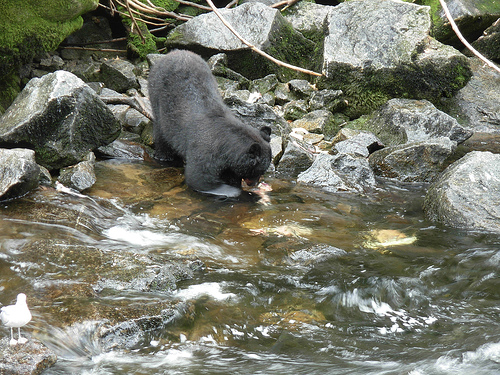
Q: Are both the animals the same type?
A: No, they are birds and bears.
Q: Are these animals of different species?
A: Yes, they are birds and bears.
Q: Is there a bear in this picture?
A: Yes, there is a bear.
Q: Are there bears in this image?
A: Yes, there is a bear.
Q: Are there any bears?
A: Yes, there is a bear.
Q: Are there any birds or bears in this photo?
A: Yes, there is a bear.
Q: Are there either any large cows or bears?
A: Yes, there is a large bear.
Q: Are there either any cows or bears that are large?
A: Yes, the bear is large.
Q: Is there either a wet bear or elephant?
A: Yes, there is a wet bear.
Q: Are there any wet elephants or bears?
A: Yes, there is a wet bear.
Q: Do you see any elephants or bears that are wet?
A: Yes, the bear is wet.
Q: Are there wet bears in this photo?
A: Yes, there is a wet bear.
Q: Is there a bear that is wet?
A: Yes, there is a bear that is wet.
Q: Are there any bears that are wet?
A: Yes, there is a bear that is wet.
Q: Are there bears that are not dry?
A: Yes, there is a wet bear.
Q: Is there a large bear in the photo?
A: Yes, there is a large bear.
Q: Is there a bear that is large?
A: Yes, there is a bear that is large.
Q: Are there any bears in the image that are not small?
A: Yes, there is a large bear.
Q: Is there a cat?
A: No, there are no cats.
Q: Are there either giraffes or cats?
A: No, there are no cats or giraffes.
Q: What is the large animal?
A: The animal is a bear.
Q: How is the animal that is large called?
A: The animal is a bear.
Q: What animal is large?
A: The animal is a bear.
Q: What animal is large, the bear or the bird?
A: The bear is large.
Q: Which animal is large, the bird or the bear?
A: The bear is large.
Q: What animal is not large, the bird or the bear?
A: The bird is not large.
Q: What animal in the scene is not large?
A: The animal is a bird.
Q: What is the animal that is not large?
A: The animal is a bird.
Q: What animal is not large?
A: The animal is a bird.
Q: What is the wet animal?
A: The animal is a bear.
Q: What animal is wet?
A: The animal is a bear.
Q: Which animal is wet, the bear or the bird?
A: The bear is wet.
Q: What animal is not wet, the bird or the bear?
A: The bird is not wet.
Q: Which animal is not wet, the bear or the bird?
A: The bird is not wet.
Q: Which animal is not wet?
A: The animal is a bird.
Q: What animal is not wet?
A: The animal is a bird.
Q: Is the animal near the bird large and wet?
A: Yes, the bear is large and wet.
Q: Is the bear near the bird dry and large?
A: No, the bear is large but wet.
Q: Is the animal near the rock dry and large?
A: No, the bear is large but wet.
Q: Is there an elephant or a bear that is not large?
A: No, there is a bear but it is large.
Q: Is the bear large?
A: Yes, the bear is large.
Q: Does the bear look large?
A: Yes, the bear is large.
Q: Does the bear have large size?
A: Yes, the bear is large.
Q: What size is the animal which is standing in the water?
A: The bear is large.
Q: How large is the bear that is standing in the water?
A: The bear is large.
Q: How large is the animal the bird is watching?
A: The bear is large.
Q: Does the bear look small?
A: No, the bear is large.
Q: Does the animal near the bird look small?
A: No, the bear is large.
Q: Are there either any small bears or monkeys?
A: No, there is a bear but it is large.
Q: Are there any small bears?
A: No, there is a bear but it is large.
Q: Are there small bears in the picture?
A: No, there is a bear but it is large.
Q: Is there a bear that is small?
A: No, there is a bear but it is large.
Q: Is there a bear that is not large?
A: No, there is a bear but it is large.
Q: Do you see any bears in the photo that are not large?
A: No, there is a bear but it is large.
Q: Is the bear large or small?
A: The bear is large.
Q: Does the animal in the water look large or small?
A: The bear is large.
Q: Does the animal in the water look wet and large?
A: Yes, the bear is wet and large.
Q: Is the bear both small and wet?
A: No, the bear is wet but large.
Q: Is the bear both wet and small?
A: No, the bear is wet but large.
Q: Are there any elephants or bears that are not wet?
A: No, there is a bear but it is wet.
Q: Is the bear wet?
A: Yes, the bear is wet.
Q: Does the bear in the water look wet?
A: Yes, the bear is wet.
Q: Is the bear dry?
A: No, the bear is wet.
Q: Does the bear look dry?
A: No, the bear is wet.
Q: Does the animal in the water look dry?
A: No, the bear is wet.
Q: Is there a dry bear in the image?
A: No, there is a bear but it is wet.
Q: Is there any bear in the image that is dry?
A: No, there is a bear but it is wet.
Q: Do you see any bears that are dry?
A: No, there is a bear but it is wet.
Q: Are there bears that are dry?
A: No, there is a bear but it is wet.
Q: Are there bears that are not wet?
A: No, there is a bear but it is wet.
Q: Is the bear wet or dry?
A: The bear is wet.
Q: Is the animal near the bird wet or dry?
A: The bear is wet.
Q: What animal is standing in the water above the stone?
A: The bear is standing in the water.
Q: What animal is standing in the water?
A: The bear is standing in the water.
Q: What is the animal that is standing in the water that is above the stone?
A: The animal is a bear.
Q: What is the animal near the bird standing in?
A: The bear is standing in the water.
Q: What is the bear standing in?
A: The bear is standing in the water.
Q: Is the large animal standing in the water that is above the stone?
A: Yes, the bear is standing in the water.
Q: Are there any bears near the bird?
A: Yes, there is a bear near the bird.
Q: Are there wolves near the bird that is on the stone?
A: No, there is a bear near the bird.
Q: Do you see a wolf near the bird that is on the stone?
A: No, there is a bear near the bird.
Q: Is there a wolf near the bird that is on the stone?
A: No, there is a bear near the bird.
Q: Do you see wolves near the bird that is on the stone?
A: No, there is a bear near the bird.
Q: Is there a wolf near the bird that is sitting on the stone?
A: No, there is a bear near the bird.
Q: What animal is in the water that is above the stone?
A: The bear is in the water.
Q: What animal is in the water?
A: The bear is in the water.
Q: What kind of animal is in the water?
A: The animal is a bear.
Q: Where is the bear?
A: The bear is in the water.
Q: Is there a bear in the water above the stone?
A: Yes, there is a bear in the water.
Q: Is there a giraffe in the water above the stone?
A: No, there is a bear in the water.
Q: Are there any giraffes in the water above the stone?
A: No, there is a bear in the water.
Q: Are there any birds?
A: Yes, there is a bird.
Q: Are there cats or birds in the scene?
A: Yes, there is a bird.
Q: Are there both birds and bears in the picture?
A: Yes, there are both a bird and a bear.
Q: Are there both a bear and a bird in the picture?
A: Yes, there are both a bird and a bear.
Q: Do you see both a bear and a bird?
A: Yes, there are both a bird and a bear.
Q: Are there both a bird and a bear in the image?
A: Yes, there are both a bird and a bear.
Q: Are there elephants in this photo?
A: No, there are no elephants.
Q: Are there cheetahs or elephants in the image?
A: No, there are no elephants or cheetahs.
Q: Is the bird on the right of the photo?
A: No, the bird is on the left of the image.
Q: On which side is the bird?
A: The bird is on the left of the image.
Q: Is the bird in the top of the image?
A: No, the bird is in the bottom of the image.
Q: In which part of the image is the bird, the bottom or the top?
A: The bird is in the bottom of the image.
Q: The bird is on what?
A: The bird is on the stone.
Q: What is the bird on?
A: The bird is on the stone.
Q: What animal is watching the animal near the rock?
A: The bird is watching the bear.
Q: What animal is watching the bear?
A: The bird is watching the bear.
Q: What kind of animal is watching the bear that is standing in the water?
A: The animal is a bird.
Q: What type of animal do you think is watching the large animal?
A: The animal is a bird.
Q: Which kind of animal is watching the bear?
A: The animal is a bird.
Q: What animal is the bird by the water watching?
A: The bird is watching the bear.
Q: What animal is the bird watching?
A: The bird is watching the bear.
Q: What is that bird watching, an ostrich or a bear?
A: The bird is watching a bear.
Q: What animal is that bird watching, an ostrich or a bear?
A: The bird is watching a bear.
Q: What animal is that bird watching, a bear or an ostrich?
A: The bird is watching a bear.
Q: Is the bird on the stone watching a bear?
A: Yes, the bird is watching a bear.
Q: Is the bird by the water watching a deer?
A: No, the bird is watching a bear.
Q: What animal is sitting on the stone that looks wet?
A: The bird is sitting on the stone.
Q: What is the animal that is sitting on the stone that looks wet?
A: The animal is a bird.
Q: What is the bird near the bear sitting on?
A: The bird is sitting on the stone.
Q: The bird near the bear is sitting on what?
A: The bird is sitting on the stone.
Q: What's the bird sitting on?
A: The bird is sitting on the stone.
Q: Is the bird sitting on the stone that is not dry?
A: Yes, the bird is sitting on the stone.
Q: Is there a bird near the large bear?
A: Yes, there is a bird near the bear.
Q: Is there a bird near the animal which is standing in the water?
A: Yes, there is a bird near the bear.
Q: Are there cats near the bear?
A: No, there is a bird near the bear.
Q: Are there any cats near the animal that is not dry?
A: No, there is a bird near the bear.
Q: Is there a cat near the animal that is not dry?
A: No, there is a bird near the bear.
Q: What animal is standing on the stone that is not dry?
A: The bird is standing on the stone.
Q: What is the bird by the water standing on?
A: The bird is standing on the stone.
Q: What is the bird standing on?
A: The bird is standing on the stone.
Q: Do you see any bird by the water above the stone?
A: Yes, there is a bird by the water.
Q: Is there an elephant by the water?
A: No, there is a bird by the water.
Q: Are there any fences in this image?
A: No, there are no fences.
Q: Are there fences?
A: No, there are no fences.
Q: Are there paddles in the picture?
A: No, there are no paddles.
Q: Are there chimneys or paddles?
A: No, there are no paddles or chimneys.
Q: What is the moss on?
A: The moss is on the rock.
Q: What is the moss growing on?
A: The moss is growing on the rock.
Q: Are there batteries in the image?
A: No, there are no batteries.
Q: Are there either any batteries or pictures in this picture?
A: No, there are no batteries or pictures.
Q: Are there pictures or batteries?
A: No, there are no batteries or pictures.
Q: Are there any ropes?
A: No, there are no ropes.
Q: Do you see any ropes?
A: No, there are no ropes.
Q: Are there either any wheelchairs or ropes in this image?
A: No, there are no ropes or wheelchairs.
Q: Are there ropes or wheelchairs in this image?
A: No, there are no ropes or wheelchairs.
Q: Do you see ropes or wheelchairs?
A: No, there are no ropes or wheelchairs.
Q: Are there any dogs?
A: No, there are no dogs.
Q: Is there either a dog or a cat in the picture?
A: No, there are no dogs or cats.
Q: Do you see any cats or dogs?
A: No, there are no dogs or cats.